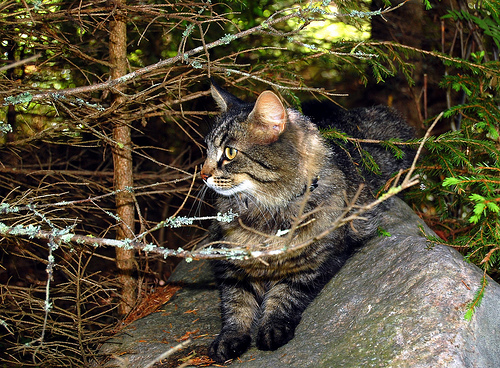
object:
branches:
[1, 0, 410, 176]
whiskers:
[213, 177, 232, 188]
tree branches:
[377, 0, 498, 322]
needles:
[322, 123, 500, 196]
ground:
[0, 192, 497, 362]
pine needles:
[460, 246, 495, 321]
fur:
[199, 84, 419, 201]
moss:
[321, 313, 404, 367]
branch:
[0, 111, 447, 262]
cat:
[187, 78, 422, 362]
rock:
[97, 192, 499, 364]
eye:
[224, 147, 241, 161]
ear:
[247, 90, 289, 145]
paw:
[255, 324, 293, 351]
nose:
[200, 172, 212, 181]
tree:
[3, 0, 446, 265]